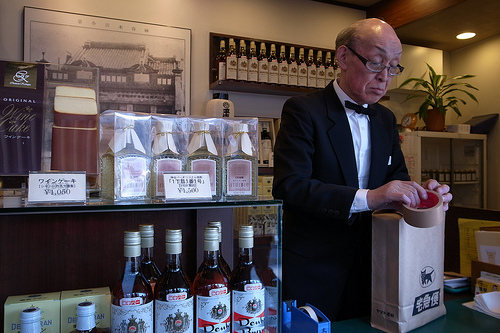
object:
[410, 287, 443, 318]
design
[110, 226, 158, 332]
bottles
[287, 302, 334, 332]
tape dispenser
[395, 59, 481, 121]
plant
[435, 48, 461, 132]
corner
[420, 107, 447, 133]
flower pot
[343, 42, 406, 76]
glasses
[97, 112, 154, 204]
liquor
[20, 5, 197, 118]
framed picture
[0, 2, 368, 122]
wall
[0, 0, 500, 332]
bar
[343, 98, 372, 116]
bow tie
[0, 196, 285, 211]
glass shelf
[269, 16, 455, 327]
man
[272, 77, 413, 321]
suit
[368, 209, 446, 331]
paper package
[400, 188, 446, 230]
packing tape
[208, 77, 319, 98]
shelf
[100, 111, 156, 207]
bottle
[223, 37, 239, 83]
bottle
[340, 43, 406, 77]
frame